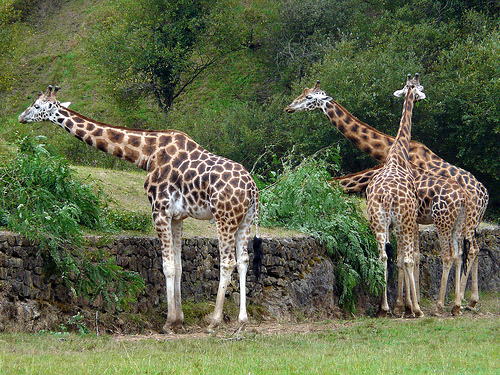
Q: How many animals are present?
A: Four.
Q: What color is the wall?
A: Grey.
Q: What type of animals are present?
A: Giraffes.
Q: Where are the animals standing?
A: Next to a wall.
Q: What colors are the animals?
A: Brown and white.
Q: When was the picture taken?
A: Daytime.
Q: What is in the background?
A: Trees.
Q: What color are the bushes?
A: Green.